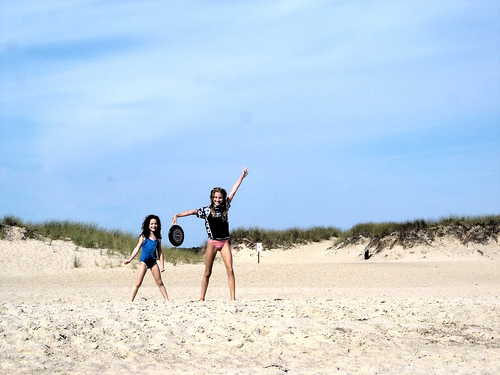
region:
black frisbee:
[168, 223, 184, 246]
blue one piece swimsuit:
[136, 233, 159, 271]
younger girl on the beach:
[123, 213, 172, 308]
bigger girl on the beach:
[169, 163, 252, 310]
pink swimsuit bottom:
[208, 236, 229, 252]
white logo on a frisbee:
[173, 225, 183, 242]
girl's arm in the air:
[229, 166, 251, 200]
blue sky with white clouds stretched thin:
[8, 7, 493, 244]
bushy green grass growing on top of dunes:
[5, 205, 490, 292]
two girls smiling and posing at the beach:
[115, 160, 250, 315]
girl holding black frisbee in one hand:
[165, 160, 250, 300]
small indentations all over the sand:
[5, 281, 487, 361]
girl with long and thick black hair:
[140, 210, 162, 240]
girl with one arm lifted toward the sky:
[165, 160, 261, 301]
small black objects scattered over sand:
[405, 300, 495, 352]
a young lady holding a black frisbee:
[167, 145, 262, 310]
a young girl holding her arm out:
[181, 152, 251, 312]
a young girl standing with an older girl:
[115, 156, 260, 317]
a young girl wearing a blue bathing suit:
[115, 195, 170, 305]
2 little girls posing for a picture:
[103, 147, 301, 337]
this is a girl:
[166, 183, 273, 308]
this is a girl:
[113, 202, 196, 332]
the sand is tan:
[263, 292, 350, 373]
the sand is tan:
[165, 309, 225, 374]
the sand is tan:
[48, 303, 128, 353]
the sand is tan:
[183, 320, 265, 367]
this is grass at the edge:
[253, 220, 336, 249]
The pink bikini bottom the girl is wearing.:
[205, 235, 229, 247]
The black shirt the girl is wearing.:
[195, 206, 232, 241]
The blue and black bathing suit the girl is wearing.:
[140, 236, 159, 268]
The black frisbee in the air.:
[167, 225, 192, 240]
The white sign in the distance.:
[252, 243, 264, 260]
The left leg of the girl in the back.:
[132, 267, 142, 298]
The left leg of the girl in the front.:
[200, 246, 212, 301]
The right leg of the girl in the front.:
[222, 245, 237, 297]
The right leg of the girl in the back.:
[152, 264, 172, 300]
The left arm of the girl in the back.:
[127, 237, 142, 264]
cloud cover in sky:
[1, 2, 496, 246]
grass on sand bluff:
[5, 211, 497, 269]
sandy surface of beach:
[2, 260, 496, 374]